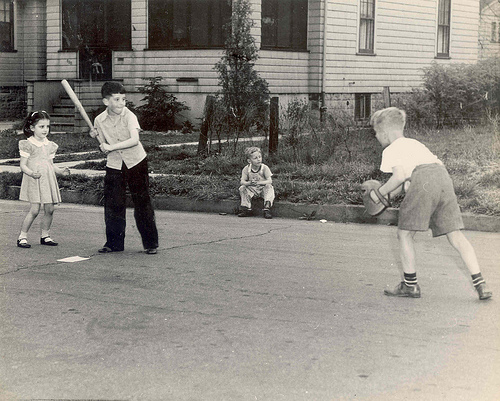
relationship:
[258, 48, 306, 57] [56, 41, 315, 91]
siding on porch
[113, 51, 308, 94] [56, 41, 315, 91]
siding on porch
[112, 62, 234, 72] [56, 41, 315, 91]
siding on porch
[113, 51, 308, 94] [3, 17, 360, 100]
siding on porch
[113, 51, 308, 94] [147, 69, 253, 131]
siding on porch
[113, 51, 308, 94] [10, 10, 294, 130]
siding on porch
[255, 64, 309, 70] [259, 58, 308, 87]
siding on porch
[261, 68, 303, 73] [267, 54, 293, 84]
siding on porch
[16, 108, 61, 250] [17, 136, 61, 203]
girl wearing a dress